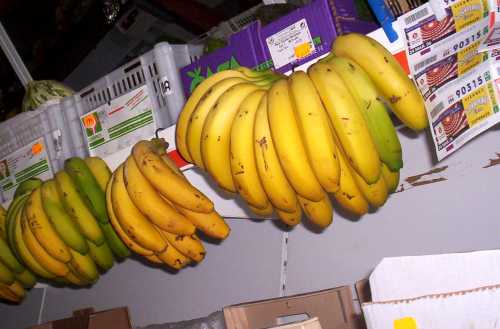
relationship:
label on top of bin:
[80, 84, 158, 158] [75, 39, 204, 159]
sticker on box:
[390, 316, 419, 328] [360, 248, 498, 329]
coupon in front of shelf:
[396, 0, 498, 164] [1, 19, 497, 204]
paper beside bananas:
[397, 1, 499, 164] [0, 32, 428, 307]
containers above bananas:
[0, 40, 203, 202] [0, 32, 428, 307]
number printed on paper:
[455, 89, 460, 99] [397, 1, 499, 164]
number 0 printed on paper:
[461, 85, 467, 95] [397, 1, 499, 164]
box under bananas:
[220, 282, 357, 328] [0, 32, 428, 307]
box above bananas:
[179, 1, 378, 99] [0, 32, 428, 307]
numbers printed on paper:
[455, 76, 483, 98] [397, 1, 499, 164]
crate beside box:
[67, 40, 203, 158] [179, 1, 378, 99]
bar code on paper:
[428, 100, 445, 119] [406, 22, 485, 138]